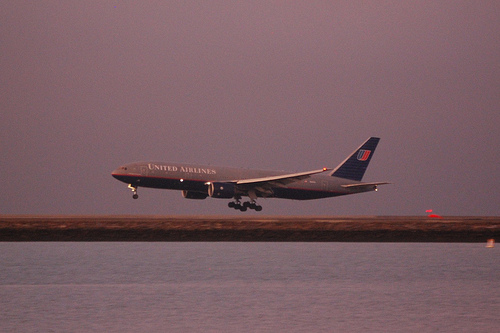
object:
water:
[0, 240, 500, 332]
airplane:
[95, 132, 439, 222]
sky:
[0, 1, 497, 218]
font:
[148, 163, 217, 175]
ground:
[0, 214, 500, 238]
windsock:
[425, 209, 445, 221]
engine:
[181, 183, 208, 200]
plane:
[113, 136, 382, 208]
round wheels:
[228, 201, 236, 208]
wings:
[342, 181, 395, 189]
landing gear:
[243, 189, 263, 210]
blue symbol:
[329, 137, 382, 181]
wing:
[216, 167, 333, 185]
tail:
[329, 135, 393, 195]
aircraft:
[110, 136, 395, 212]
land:
[0, 213, 498, 240]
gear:
[255, 205, 263, 212]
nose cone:
[111, 165, 125, 175]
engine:
[207, 182, 235, 199]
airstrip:
[0, 213, 500, 229]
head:
[111, 161, 141, 184]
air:
[0, 0, 500, 333]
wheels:
[132, 194, 139, 200]